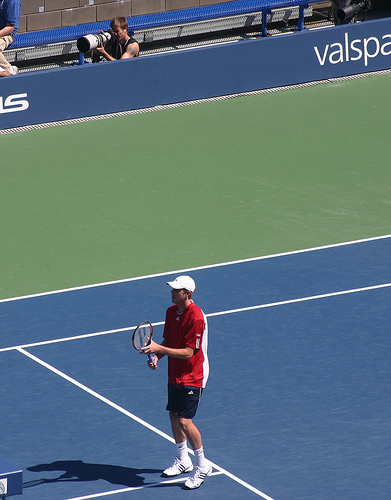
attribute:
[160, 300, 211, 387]
shirt — red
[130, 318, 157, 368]
racket — tennis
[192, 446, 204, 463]
socks — black, white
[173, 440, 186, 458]
socks — black, white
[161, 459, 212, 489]
shoes — white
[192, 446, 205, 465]
sock — black, white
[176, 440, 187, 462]
sock — black, white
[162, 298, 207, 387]
shirt — red , white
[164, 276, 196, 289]
cap — white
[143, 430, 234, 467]
socks — white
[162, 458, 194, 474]
shoes — white, black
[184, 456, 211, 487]
shoes — black, white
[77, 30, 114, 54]
camera lens — large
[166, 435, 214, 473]
socks — white 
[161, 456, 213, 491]
shoes — white 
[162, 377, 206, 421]
shorts — black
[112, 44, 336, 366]
lines — white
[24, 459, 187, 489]
shadow — man's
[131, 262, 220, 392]
shirt — red, tee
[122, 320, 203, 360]
arm — man's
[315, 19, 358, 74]
letters — white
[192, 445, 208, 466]
sock — white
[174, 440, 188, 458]
sock — white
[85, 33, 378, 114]
wall — blue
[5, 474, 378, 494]
court — tennis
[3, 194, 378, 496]
court — blue, tennis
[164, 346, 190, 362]
tattoo — large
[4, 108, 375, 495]
court — tennis, blue, green